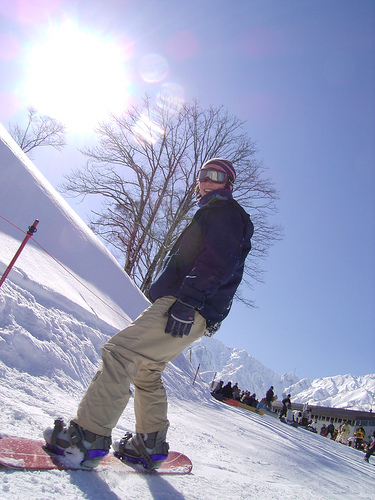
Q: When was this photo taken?
A: During the day.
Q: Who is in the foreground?
A: A snowboarder.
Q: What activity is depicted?
A: Snowboarding.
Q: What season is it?
A: Winter.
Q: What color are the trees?
A: Brown.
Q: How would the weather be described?
A: Sunny and clear skies.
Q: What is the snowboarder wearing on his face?
A: Goggles.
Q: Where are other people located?
A: In the background near the building.